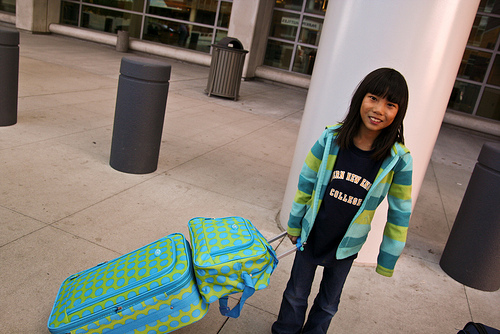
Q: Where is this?
A: This is at the sidewalk.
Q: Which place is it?
A: It is a sidewalk.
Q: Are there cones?
A: No, there are no cones.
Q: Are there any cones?
A: No, there are no cones.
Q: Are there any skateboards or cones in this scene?
A: No, there are no cones or skateboards.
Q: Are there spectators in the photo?
A: No, there are no spectators.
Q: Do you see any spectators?
A: No, there are no spectators.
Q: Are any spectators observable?
A: No, there are no spectators.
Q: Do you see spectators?
A: No, there are no spectators.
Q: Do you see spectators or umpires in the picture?
A: No, there are no spectators or umpires.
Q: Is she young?
A: Yes, the girl is young.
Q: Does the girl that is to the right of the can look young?
A: Yes, the girl is young.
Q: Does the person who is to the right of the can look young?
A: Yes, the girl is young.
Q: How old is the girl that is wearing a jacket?
A: The girl is young.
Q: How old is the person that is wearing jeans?
A: The girl is young.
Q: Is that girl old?
A: No, the girl is young.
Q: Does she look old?
A: No, the girl is young.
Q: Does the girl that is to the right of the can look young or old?
A: The girl is young.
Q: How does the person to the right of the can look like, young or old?
A: The girl is young.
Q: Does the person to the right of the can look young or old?
A: The girl is young.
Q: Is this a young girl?
A: Yes, this is a young girl.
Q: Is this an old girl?
A: No, this is a young girl.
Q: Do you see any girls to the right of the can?
A: Yes, there is a girl to the right of the can.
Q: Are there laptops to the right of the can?
A: No, there is a girl to the right of the can.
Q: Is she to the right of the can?
A: Yes, the girl is to the right of the can.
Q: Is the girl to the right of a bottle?
A: No, the girl is to the right of the can.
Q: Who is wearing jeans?
A: The girl is wearing jeans.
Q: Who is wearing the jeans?
A: The girl is wearing jeans.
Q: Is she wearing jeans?
A: Yes, the girl is wearing jeans.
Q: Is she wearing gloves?
A: No, the girl is wearing jeans.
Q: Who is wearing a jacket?
A: The girl is wearing a jacket.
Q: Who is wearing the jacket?
A: The girl is wearing a jacket.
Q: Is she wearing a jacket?
A: Yes, the girl is wearing a jacket.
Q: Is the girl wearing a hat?
A: No, the girl is wearing a jacket.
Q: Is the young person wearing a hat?
A: No, the girl is wearing a jacket.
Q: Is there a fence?
A: No, there are no fences.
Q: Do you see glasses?
A: No, there are no glasses.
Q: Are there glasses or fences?
A: No, there are no glasses or fences.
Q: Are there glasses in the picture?
A: No, there are no glasses.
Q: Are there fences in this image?
A: No, there are no fences.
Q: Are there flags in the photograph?
A: No, there are no flags.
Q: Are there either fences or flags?
A: No, there are no flags or fences.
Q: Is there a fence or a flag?
A: No, there are no flags or fences.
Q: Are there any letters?
A: Yes, there are letters.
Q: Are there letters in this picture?
A: Yes, there are letters.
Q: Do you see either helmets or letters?
A: Yes, there are letters.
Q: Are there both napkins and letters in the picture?
A: No, there are letters but no napkins.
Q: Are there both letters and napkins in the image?
A: No, there are letters but no napkins.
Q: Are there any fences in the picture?
A: No, there are no fences.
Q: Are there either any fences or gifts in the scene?
A: No, there are no fences or gifts.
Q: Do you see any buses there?
A: No, there are no buses.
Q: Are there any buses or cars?
A: No, there are no buses or cars.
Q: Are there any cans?
A: Yes, there is a can.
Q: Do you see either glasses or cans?
A: Yes, there is a can.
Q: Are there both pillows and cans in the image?
A: No, there is a can but no pillows.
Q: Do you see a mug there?
A: No, there are no mugs.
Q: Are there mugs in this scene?
A: No, there are no mugs.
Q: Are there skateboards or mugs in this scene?
A: No, there are no mugs or skateboards.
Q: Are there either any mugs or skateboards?
A: No, there are no mugs or skateboards.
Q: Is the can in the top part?
A: Yes, the can is in the top of the image.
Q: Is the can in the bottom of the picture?
A: No, the can is in the top of the image.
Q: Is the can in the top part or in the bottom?
A: The can is in the top of the image.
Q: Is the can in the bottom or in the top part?
A: The can is in the top of the image.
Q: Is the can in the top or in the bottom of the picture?
A: The can is in the top of the image.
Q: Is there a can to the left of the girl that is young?
A: Yes, there is a can to the left of the girl.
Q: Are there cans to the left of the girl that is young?
A: Yes, there is a can to the left of the girl.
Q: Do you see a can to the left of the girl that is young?
A: Yes, there is a can to the left of the girl.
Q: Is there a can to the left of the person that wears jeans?
A: Yes, there is a can to the left of the girl.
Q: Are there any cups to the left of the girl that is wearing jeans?
A: No, there is a can to the left of the girl.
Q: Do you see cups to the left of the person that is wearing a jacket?
A: No, there is a can to the left of the girl.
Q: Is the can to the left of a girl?
A: Yes, the can is to the left of a girl.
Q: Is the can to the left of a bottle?
A: No, the can is to the left of a girl.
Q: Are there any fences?
A: No, there are no fences.